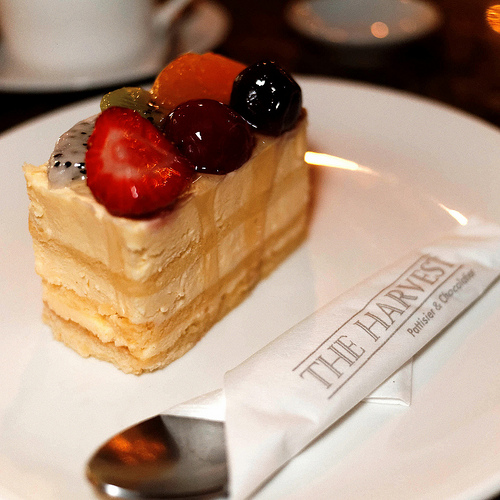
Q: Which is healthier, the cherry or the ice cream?
A: The cherry is healthier than the ice cream.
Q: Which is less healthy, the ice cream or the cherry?
A: The ice cream is less healthy than the cherry.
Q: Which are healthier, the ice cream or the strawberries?
A: The strawberries are healthier than the ice cream.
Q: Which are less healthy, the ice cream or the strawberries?
A: The ice cream are less healthy than the strawberries.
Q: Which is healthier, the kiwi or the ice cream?
A: The kiwi is healthier than the ice cream.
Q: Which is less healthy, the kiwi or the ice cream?
A: The ice cream is less healthy than the kiwi.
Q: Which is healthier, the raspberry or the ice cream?
A: The raspberry is healthier than the ice cream.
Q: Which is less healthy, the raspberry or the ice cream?
A: The ice cream is less healthy than the raspberry.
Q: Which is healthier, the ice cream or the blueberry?
A: The blueberry is healthier than the ice cream.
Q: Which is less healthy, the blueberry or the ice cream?
A: The ice cream is less healthy than the blueberry.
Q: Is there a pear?
A: No, there are no pears.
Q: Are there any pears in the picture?
A: No, there are no pears.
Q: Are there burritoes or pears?
A: No, there are no pears or burritoes.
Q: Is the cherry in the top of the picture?
A: Yes, the cherry is in the top of the image.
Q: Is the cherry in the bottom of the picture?
A: No, the cherry is in the top of the image.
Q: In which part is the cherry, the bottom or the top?
A: The cherry is in the top of the image.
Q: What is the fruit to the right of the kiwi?
A: The fruit is a cherry.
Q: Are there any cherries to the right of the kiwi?
A: Yes, there is a cherry to the right of the kiwi.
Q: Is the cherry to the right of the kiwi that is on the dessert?
A: Yes, the cherry is to the right of the kiwi.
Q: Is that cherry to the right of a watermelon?
A: No, the cherry is to the right of the kiwi.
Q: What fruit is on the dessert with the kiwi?
A: The fruit is a cherry.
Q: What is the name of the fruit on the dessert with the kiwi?
A: The fruit is a cherry.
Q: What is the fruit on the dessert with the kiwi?
A: The fruit is a cherry.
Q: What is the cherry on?
A: The cherry is on the dessert.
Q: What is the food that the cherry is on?
A: The food is a dessert.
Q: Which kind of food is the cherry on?
A: The cherry is on the dessert.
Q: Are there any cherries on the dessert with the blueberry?
A: Yes, there is a cherry on the dessert.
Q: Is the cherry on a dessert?
A: Yes, the cherry is on a dessert.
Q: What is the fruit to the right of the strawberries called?
A: The fruit is a cherry.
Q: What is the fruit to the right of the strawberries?
A: The fruit is a cherry.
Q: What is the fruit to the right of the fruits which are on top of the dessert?
A: The fruit is a cherry.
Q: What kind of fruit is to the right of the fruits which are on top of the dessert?
A: The fruit is a cherry.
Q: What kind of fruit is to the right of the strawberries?
A: The fruit is a cherry.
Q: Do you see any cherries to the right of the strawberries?
A: Yes, there is a cherry to the right of the strawberries.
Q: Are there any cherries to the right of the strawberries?
A: Yes, there is a cherry to the right of the strawberries.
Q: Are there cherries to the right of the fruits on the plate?
A: Yes, there is a cherry to the right of the strawberries.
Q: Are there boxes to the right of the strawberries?
A: No, there is a cherry to the right of the strawberries.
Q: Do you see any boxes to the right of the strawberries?
A: No, there is a cherry to the right of the strawberries.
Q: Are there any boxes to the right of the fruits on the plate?
A: No, there is a cherry to the right of the strawberries.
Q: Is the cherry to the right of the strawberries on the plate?
A: Yes, the cherry is to the right of the strawberries.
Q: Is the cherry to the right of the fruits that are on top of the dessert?
A: Yes, the cherry is to the right of the strawberries.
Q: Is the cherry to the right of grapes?
A: No, the cherry is to the right of the strawberries.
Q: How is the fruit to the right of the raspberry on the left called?
A: The fruit is a cherry.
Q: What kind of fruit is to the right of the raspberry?
A: The fruit is a cherry.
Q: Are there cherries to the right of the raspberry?
A: Yes, there is a cherry to the right of the raspberry.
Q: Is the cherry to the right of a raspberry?
A: Yes, the cherry is to the right of a raspberry.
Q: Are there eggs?
A: No, there are no eggs.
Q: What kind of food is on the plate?
A: The food is a dessert.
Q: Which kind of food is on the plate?
A: The food is a dessert.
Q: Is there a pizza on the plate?
A: No, there is a dessert on the plate.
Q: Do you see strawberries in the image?
A: Yes, there are strawberries.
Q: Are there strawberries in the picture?
A: Yes, there are strawberries.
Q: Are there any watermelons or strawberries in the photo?
A: Yes, there are strawberries.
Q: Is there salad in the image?
A: No, there is no salad.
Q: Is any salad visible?
A: No, there is no salad.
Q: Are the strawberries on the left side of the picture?
A: Yes, the strawberries are on the left of the image.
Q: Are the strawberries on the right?
A: No, the strawberries are on the left of the image.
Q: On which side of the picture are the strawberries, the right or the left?
A: The strawberries are on the left of the image.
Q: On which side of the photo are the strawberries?
A: The strawberries are on the left of the image.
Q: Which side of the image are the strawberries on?
A: The strawberries are on the left of the image.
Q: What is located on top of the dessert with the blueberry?
A: The strawberries are on top of the dessert.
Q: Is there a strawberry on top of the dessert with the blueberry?
A: Yes, there are strawberries on top of the dessert.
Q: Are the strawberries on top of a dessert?
A: Yes, the strawberries are on top of a dessert.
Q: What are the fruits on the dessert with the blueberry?
A: The fruits are strawberries.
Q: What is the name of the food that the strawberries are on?
A: The food is a dessert.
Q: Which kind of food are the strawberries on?
A: The strawberries are on the dessert.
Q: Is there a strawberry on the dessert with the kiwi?
A: Yes, there are strawberries on the dessert.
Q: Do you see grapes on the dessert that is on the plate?
A: No, there are strawberries on the dessert.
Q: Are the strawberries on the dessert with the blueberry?
A: Yes, the strawberries are on the dessert.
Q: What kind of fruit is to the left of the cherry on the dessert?
A: The fruits are strawberries.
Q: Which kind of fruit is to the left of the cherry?
A: The fruits are strawberries.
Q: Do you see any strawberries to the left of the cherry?
A: Yes, there are strawberries to the left of the cherry.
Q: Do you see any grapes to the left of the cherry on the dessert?
A: No, there are strawberries to the left of the cherry.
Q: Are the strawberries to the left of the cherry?
A: Yes, the strawberries are to the left of the cherry.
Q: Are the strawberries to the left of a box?
A: No, the strawberries are to the left of the cherry.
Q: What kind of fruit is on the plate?
A: The fruits are strawberries.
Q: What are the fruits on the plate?
A: The fruits are strawberries.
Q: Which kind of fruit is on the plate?
A: The fruits are strawberries.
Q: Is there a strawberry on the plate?
A: Yes, there are strawberries on the plate.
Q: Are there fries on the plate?
A: No, there are strawberries on the plate.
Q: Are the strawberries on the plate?
A: Yes, the strawberries are on the plate.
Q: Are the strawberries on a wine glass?
A: No, the strawberries are on the plate.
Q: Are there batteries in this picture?
A: No, there are no batteries.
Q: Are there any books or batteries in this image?
A: No, there are no batteries or books.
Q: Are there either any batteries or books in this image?
A: No, there are no batteries or books.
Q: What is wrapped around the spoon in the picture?
A: The napkin is wrapped around the spoon.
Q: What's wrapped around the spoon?
A: The napkin is wrapped around the spoon.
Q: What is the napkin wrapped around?
A: The napkin is wrapped around the spoon.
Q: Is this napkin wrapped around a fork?
A: No, the napkin is wrapped around the spoon.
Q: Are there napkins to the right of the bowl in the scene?
A: Yes, there is a napkin to the right of the bowl.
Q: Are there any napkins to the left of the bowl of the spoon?
A: No, the napkin is to the right of the bowl.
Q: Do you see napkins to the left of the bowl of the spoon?
A: No, the napkin is to the right of the bowl.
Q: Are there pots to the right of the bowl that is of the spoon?
A: No, there is a napkin to the right of the bowl.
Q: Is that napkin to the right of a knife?
A: No, the napkin is to the right of a bowl.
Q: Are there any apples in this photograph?
A: No, there are no apples.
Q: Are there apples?
A: No, there are no apples.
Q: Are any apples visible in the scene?
A: No, there are no apples.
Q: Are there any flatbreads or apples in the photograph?
A: No, there are no apples or flatbreads.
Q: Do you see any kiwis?
A: Yes, there is a kiwi.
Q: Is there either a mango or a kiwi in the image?
A: Yes, there is a kiwi.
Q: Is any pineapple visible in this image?
A: No, there are no pineapples.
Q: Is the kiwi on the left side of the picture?
A: Yes, the kiwi is on the left of the image.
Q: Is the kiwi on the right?
A: No, the kiwi is on the left of the image.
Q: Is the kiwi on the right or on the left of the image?
A: The kiwi is on the left of the image.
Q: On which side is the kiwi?
A: The kiwi is on the left of the image.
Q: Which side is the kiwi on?
A: The kiwi is on the left of the image.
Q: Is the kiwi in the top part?
A: Yes, the kiwi is in the top of the image.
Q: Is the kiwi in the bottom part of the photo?
A: No, the kiwi is in the top of the image.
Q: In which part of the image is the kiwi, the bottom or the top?
A: The kiwi is in the top of the image.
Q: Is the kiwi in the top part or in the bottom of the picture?
A: The kiwi is in the top of the image.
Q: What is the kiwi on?
A: The kiwi is on the dessert.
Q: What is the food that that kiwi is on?
A: The food is a dessert.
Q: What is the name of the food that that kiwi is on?
A: The food is a dessert.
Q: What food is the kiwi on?
A: The kiwi is on the dessert.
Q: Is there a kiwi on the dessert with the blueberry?
A: Yes, there is a kiwi on the dessert.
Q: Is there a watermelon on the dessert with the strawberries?
A: No, there is a kiwi on the dessert.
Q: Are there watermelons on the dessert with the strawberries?
A: No, there is a kiwi on the dessert.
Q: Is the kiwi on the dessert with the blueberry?
A: Yes, the kiwi is on the dessert.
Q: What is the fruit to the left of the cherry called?
A: The fruit is a kiwi.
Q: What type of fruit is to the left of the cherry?
A: The fruit is a kiwi.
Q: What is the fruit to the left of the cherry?
A: The fruit is a kiwi.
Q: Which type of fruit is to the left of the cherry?
A: The fruit is a kiwi.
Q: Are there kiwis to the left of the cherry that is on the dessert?
A: Yes, there is a kiwi to the left of the cherry.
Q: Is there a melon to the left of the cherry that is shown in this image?
A: No, there is a kiwi to the left of the cherry.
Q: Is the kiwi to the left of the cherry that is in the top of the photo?
A: Yes, the kiwi is to the left of the cherry.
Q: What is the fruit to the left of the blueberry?
A: The fruit is a kiwi.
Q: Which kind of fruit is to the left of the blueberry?
A: The fruit is a kiwi.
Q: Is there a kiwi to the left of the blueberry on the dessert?
A: Yes, there is a kiwi to the left of the blueberry.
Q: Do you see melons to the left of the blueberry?
A: No, there is a kiwi to the left of the blueberry.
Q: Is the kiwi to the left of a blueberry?
A: Yes, the kiwi is to the left of a blueberry.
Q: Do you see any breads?
A: No, there are no breads.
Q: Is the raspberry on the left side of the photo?
A: Yes, the raspberry is on the left of the image.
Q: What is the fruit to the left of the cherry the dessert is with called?
A: The fruit is a raspberry.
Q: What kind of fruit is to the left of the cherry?
A: The fruit is a raspberry.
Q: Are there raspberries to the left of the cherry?
A: Yes, there is a raspberry to the left of the cherry.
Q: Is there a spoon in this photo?
A: Yes, there is a spoon.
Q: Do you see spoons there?
A: Yes, there is a spoon.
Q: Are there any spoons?
A: Yes, there is a spoon.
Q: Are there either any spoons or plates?
A: Yes, there is a spoon.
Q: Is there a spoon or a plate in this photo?
A: Yes, there is a spoon.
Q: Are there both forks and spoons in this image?
A: No, there is a spoon but no forks.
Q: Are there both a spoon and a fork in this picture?
A: No, there is a spoon but no forks.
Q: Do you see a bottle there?
A: No, there are no bottles.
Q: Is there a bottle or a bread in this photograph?
A: No, there are no bottles or breads.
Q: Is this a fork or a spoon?
A: This is a spoon.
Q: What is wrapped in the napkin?
A: The spoon is wrapped in the napkin.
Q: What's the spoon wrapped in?
A: The spoon is wrapped in a napkin.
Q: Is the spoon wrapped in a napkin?
A: Yes, the spoon is wrapped in a napkin.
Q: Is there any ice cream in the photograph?
A: Yes, there is ice cream.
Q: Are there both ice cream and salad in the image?
A: No, there is ice cream but no salad.